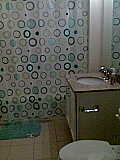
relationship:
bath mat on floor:
[0, 119, 41, 139] [0, 114, 70, 159]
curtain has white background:
[0, 0, 90, 120] [0, 0, 88, 117]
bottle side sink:
[109, 66, 117, 86] [74, 74, 106, 84]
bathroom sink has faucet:
[78, 75, 103, 86] [96, 66, 113, 79]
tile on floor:
[2, 138, 43, 158] [0, 114, 70, 159]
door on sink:
[68, 86, 76, 141] [64, 65, 119, 145]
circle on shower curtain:
[63, 28, 69, 36] [0, 1, 87, 74]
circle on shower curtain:
[26, 63, 32, 70] [0, 1, 87, 74]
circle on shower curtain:
[23, 29, 30, 37] [0, 1, 87, 74]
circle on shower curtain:
[63, 62, 70, 69] [0, 1, 87, 74]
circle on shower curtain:
[39, 54, 45, 61] [0, 1, 87, 74]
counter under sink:
[65, 73, 118, 143] [65, 66, 119, 89]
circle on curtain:
[16, 104, 24, 111] [0, 0, 90, 120]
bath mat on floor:
[0, 119, 41, 139] [19, 141, 40, 153]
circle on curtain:
[28, 95, 35, 102] [7, 6, 85, 94]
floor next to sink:
[0, 114, 70, 159] [62, 64, 118, 101]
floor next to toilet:
[0, 114, 70, 159] [57, 136, 119, 159]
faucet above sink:
[95, 61, 118, 87] [76, 76, 104, 85]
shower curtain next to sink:
[0, 0, 89, 121] [64, 63, 118, 93]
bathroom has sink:
[1, 1, 118, 158] [64, 63, 118, 93]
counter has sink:
[65, 73, 118, 143] [76, 76, 104, 85]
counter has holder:
[65, 73, 118, 143] [84, 106, 99, 114]